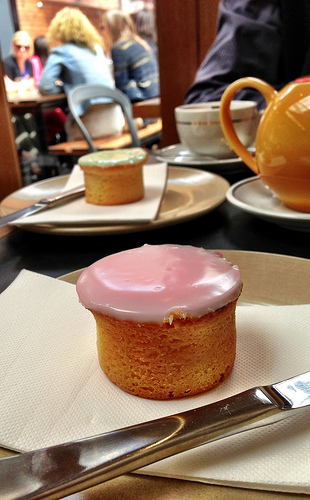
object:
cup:
[174, 102, 265, 160]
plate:
[0, 250, 310, 500]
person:
[37, 7, 126, 139]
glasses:
[14, 45, 31, 53]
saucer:
[224, 172, 310, 220]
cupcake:
[77, 147, 148, 205]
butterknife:
[0, 183, 85, 228]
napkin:
[9, 159, 169, 225]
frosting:
[78, 147, 148, 168]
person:
[183, 1, 310, 112]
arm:
[182, 28, 300, 105]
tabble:
[0, 148, 308, 293]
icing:
[76, 243, 241, 319]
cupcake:
[75, 242, 244, 401]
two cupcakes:
[75, 146, 242, 400]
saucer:
[154, 142, 257, 165]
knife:
[0, 371, 310, 500]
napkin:
[0, 268, 310, 493]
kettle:
[219, 76, 310, 213]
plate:
[0, 163, 230, 233]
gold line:
[174, 115, 260, 126]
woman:
[0, 29, 39, 103]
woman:
[99, 8, 159, 103]